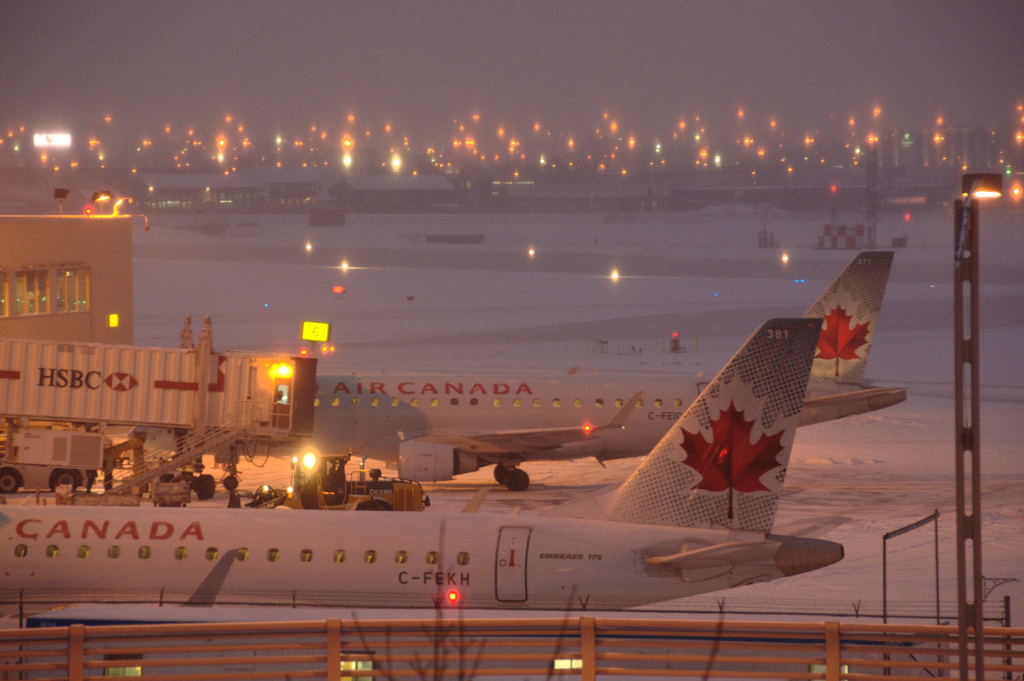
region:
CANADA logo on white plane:
[13, 505, 206, 543]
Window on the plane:
[38, 531, 51, 557]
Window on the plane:
[95, 535, 112, 554]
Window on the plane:
[130, 535, 141, 549]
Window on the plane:
[162, 535, 181, 555]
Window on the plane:
[194, 531, 207, 550]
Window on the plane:
[228, 536, 249, 565]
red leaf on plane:
[673, 407, 803, 532]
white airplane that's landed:
[2, 319, 847, 664]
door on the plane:
[471, 520, 545, 618]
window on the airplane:
[256, 540, 288, 566]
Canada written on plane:
[10, 514, 213, 553]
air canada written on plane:
[335, 368, 554, 406]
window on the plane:
[100, 536, 133, 571]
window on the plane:
[195, 546, 231, 576]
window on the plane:
[447, 544, 461, 561]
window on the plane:
[425, 544, 441, 567]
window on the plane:
[386, 544, 402, 563]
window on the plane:
[368, 549, 376, 566]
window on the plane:
[334, 534, 339, 569]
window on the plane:
[254, 538, 290, 567]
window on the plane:
[77, 538, 94, 564]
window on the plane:
[155, 541, 185, 560]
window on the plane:
[204, 528, 252, 554]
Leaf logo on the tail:
[675, 405, 789, 517]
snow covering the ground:
[7, 3, 1010, 624]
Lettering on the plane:
[8, 514, 218, 549]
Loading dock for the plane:
[2, 326, 317, 460]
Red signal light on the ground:
[664, 325, 684, 346]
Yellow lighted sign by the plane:
[294, 315, 339, 348]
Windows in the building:
[0, 249, 98, 323]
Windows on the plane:
[314, 391, 689, 415]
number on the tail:
[754, 319, 799, 345]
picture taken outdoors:
[30, 24, 955, 484]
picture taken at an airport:
[33, 40, 1017, 661]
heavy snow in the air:
[114, 35, 909, 391]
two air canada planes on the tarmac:
[215, 340, 854, 584]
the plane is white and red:
[152, 445, 950, 588]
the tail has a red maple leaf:
[661, 278, 769, 547]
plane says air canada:
[330, 360, 549, 424]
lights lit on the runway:
[272, 208, 813, 304]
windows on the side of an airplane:
[16, 534, 65, 566]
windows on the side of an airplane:
[429, 389, 544, 425]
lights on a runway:
[261, 217, 404, 303]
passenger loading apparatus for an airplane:
[5, 324, 350, 470]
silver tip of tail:
[763, 519, 850, 609]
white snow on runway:
[804, 458, 1008, 621]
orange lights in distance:
[333, 72, 842, 180]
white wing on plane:
[17, 546, 318, 657]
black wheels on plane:
[476, 443, 549, 498]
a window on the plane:
[441, 551, 484, 586]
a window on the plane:
[377, 487, 426, 586]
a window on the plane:
[430, 519, 453, 565]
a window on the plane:
[327, 525, 367, 571]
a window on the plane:
[260, 519, 318, 583]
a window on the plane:
[231, 537, 283, 580]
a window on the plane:
[231, 557, 280, 595]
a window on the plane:
[187, 540, 245, 598]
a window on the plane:
[111, 525, 189, 598]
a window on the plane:
[35, 496, 108, 583]